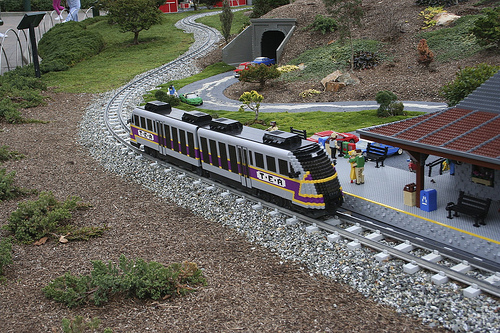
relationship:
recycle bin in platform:
[420, 179, 436, 216] [373, 171, 498, 261]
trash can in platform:
[403, 181, 418, 208] [329, 146, 498, 240]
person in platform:
[347, 144, 366, 184] [366, 169, 393, 195]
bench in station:
[445, 186, 494, 228] [353, 66, 497, 229]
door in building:
[166, 2, 179, 14] [153, 0, 247, 15]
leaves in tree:
[241, 88, 265, 104] [227, 86, 281, 138]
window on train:
[185, 132, 196, 155] [127, 102, 342, 213]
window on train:
[276, 158, 289, 178] [127, 102, 342, 213]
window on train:
[261, 151, 281, 171] [127, 102, 342, 213]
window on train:
[255, 155, 268, 170] [127, 102, 342, 213]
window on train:
[199, 138, 234, 168] [127, 102, 342, 213]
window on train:
[177, 128, 188, 153] [127, 102, 342, 213]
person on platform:
[347, 144, 366, 184] [310, 133, 483, 259]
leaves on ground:
[30, 229, 77, 250] [8, 169, 218, 314]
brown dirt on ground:
[8, 87, 418, 330] [9, 6, 493, 330]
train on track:
[105, 89, 361, 211] [108, 5, 498, 295]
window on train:
[199, 138, 234, 168] [144, 123, 334, 212]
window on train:
[261, 151, 281, 171] [144, 123, 334, 212]